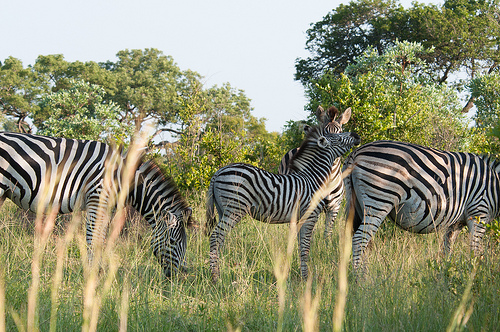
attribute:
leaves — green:
[0, 1, 499, 210]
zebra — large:
[3, 127, 194, 287]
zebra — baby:
[204, 133, 352, 269]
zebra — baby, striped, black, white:
[203, 120, 358, 279]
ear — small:
[315, 134, 329, 146]